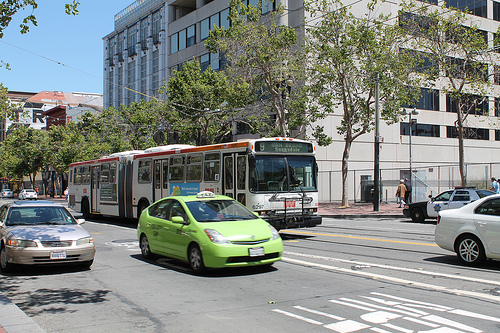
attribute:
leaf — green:
[176, 75, 257, 110]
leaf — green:
[12, 138, 29, 150]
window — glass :
[397, 118, 442, 137]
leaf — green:
[53, 114, 89, 136]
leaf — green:
[314, 124, 325, 129]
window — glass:
[398, 80, 438, 106]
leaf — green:
[17, 132, 26, 141]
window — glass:
[200, 19, 211, 39]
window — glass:
[446, 22, 486, 47]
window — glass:
[395, 44, 440, 78]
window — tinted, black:
[444, 54, 486, 88]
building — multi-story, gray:
[99, 0, 499, 201]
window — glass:
[446, 92, 488, 114]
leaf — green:
[87, 127, 102, 141]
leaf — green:
[82, 147, 93, 156]